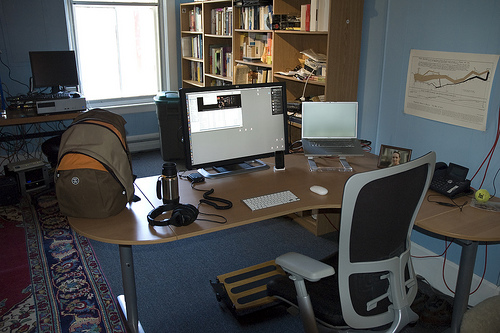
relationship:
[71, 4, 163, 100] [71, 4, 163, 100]
window has window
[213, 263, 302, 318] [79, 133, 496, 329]
foot rest under desk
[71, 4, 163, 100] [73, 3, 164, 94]
window allows in sunlight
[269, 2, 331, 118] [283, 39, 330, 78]
bookshelf has papers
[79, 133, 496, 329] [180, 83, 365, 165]
desk has two monitors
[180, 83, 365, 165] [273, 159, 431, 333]
computer has chair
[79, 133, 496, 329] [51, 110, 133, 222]
desk has backpack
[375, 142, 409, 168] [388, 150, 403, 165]
picture of a lady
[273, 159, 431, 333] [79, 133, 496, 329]
chair by desk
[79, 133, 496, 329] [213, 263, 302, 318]
desk above foot rest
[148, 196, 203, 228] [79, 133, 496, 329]
headphones are on desk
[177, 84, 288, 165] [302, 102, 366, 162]
monitor next to laptop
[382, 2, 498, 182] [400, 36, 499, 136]
wall has poster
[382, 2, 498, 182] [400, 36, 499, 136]
wall has on it a paper graph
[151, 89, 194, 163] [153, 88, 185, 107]
garbage can has a green lid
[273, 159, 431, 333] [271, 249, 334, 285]
chair has an arm rest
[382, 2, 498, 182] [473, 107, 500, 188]
wall has electric cords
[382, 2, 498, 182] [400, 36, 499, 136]
wall has a chart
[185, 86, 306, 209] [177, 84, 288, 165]
computer has a screen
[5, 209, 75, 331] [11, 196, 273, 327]
rug on floor